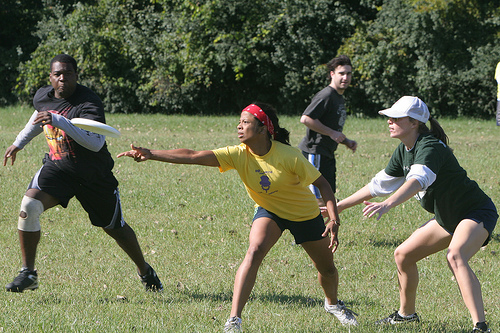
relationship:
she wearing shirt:
[130, 100, 367, 327] [211, 137, 326, 224]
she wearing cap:
[317, 90, 499, 326] [374, 96, 439, 125]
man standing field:
[3, 48, 164, 298] [1, 87, 495, 327]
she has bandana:
[113, 100, 371, 333] [238, 100, 273, 137]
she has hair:
[113, 100, 371, 333] [244, 97, 296, 147]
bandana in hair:
[238, 100, 273, 137] [244, 97, 296, 147]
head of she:
[218, 97, 295, 153] [113, 100, 371, 333]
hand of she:
[112, 136, 154, 163] [113, 100, 371, 333]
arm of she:
[151, 142, 233, 174] [113, 100, 371, 333]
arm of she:
[293, 157, 340, 214] [113, 100, 371, 333]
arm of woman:
[323, 168, 395, 211] [327, 86, 498, 331]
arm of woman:
[383, 149, 441, 209] [327, 86, 498, 331]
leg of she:
[190, 212, 302, 330] [113, 100, 371, 333]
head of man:
[52, 54, 77, 100] [3, 48, 164, 298]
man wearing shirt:
[35, 48, 144, 232] [32, 85, 116, 175]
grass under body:
[335, 214, 417, 248] [301, 54, 358, 252]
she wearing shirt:
[113, 100, 371, 333] [211, 137, 326, 224]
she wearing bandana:
[113, 100, 371, 333] [241, 103, 279, 135]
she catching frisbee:
[113, 100, 371, 333] [67, 105, 122, 141]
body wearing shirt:
[301, 55, 359, 223] [296, 85, 349, 153]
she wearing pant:
[113, 100, 371, 333] [251, 207, 327, 244]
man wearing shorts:
[3, 48, 164, 298] [15, 118, 145, 259]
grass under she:
[0, 106, 500, 333] [113, 100, 371, 333]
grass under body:
[0, 106, 500, 333] [110, 100, 382, 333]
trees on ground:
[18, 52, 138, 113] [4, 98, 496, 328]